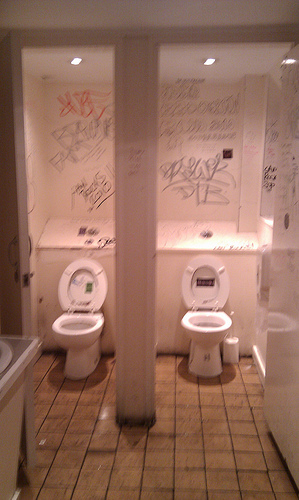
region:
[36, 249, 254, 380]
two toilets are in the bathroom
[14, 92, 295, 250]
writing on wall is black and orange in color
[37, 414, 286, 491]
ceramic tile on floor is tan in color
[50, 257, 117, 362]
toilet seat is in the up position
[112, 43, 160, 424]
single column separates the toilets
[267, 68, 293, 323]
mirror to the right of toilet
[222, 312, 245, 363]
toilet bowl cleaner is to right of toilet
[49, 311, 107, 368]
toilet bowl is white in color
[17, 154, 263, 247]
walls are of a white color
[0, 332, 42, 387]
sink is to the left of toilets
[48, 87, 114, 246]
graffiti covers the wall of the bathroom stall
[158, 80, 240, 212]
graffiti covers the wall of the bathroom stall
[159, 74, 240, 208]
graffiti is above the toilet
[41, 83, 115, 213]
graffiti is above the toilet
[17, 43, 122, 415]
bathroom stall is vacant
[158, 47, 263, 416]
bathroom stall is vacant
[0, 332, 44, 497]
bathroom countertop is empty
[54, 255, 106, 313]
toilet seat lid is up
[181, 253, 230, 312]
toilet seat lid is up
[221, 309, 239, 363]
toilet brush is put away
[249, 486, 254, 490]
part of a floor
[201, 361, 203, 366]
part of a toilet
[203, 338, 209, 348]
edge of a toilet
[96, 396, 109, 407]
part of a shadow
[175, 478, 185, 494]
part of the floor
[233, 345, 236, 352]
part of a scrub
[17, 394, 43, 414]
part of a sink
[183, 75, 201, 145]
There is graffitti here that is very visible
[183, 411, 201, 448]
There are brown tiles that are on the bottom of the bathroom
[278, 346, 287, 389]
There is white that is on the side of the bathroom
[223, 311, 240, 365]
There is a toilet bowl cleaner that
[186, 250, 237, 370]
There is a toilet that is very visible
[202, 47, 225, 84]
There are very bright lights that are visible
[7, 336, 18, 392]
There is a sink that is visible here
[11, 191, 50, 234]
There is a white wall that is visible here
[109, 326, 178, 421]
There is a white placard here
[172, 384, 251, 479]
Dully looking floor tiles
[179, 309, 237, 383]
White colored toilet seat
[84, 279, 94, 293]
A small green patch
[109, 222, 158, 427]
Tall thick centre ark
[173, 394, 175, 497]
A narrow black line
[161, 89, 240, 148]
Poorly written wall graffiti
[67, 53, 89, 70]
Small luminous ceiling light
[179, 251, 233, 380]
A clean opened toilet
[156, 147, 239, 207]
Big syllabled wall writing